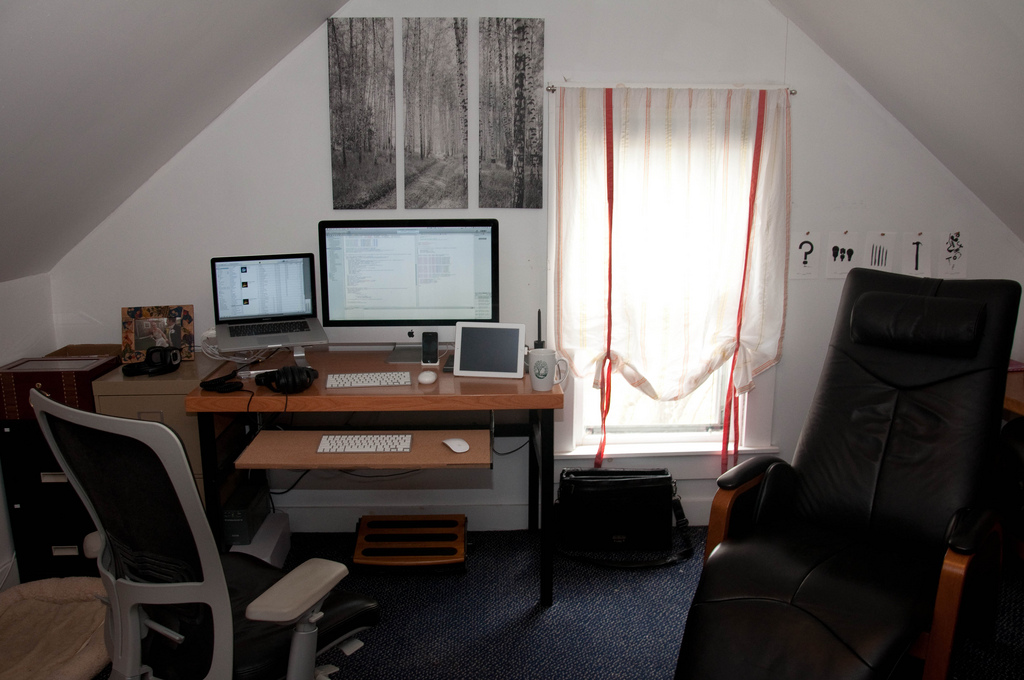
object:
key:
[354, 437, 367, 449]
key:
[361, 435, 375, 448]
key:
[373, 431, 390, 443]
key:
[325, 435, 333, 449]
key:
[328, 371, 345, 379]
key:
[351, 371, 364, 383]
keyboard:
[321, 359, 423, 394]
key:
[374, 371, 389, 379]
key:
[391, 369, 407, 377]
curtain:
[543, 72, 801, 461]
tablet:
[450, 317, 530, 382]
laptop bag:
[534, 452, 702, 576]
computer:
[308, 205, 518, 366]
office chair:
[24, 379, 357, 676]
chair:
[659, 253, 1021, 677]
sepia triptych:
[311, 4, 556, 221]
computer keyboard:
[302, 416, 430, 465]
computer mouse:
[426, 428, 484, 459]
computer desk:
[179, 334, 584, 607]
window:
[539, 74, 798, 464]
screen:
[452, 321, 526, 377]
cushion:
[211, 539, 386, 659]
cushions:
[674, 264, 1024, 679]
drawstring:
[591, 80, 774, 480]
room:
[2, 0, 1021, 676]